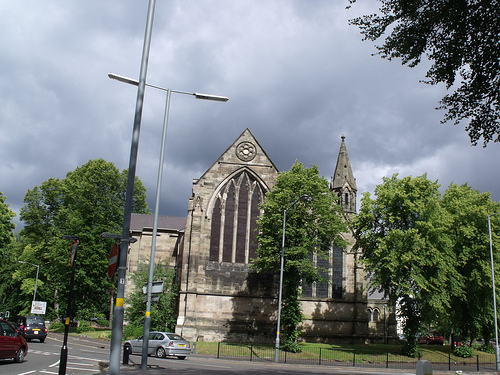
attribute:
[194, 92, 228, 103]
street light — white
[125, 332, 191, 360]
car — gray, grey, silver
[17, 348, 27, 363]
tire — black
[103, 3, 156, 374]
pole — metal, tall, gray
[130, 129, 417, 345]
church — large, stone, tall, grey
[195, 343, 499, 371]
fence — dark, black, small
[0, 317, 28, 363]
car — red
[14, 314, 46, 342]
car — black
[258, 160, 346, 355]
tree — green, tall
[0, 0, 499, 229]
sky — blue, cloudy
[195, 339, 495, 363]
grass — green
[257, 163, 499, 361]
trees — green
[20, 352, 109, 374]
lines — white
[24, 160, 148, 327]
tree — green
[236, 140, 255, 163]
circle — ornate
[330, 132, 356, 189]
steeple — pointed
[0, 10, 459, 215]
clouds — dark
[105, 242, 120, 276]
sign — red, white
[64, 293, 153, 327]
stripes — yellow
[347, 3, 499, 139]
leaves — green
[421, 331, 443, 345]
car — parked, red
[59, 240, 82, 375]
pole — brown, small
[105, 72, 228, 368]
pole — tall